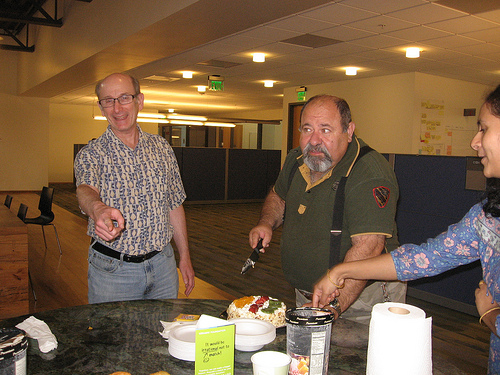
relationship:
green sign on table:
[194, 323, 234, 373] [0, 300, 287, 374]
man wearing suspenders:
[252, 88, 398, 289] [237, 140, 406, 302]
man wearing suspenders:
[75, 73, 195, 303] [282, 143, 374, 269]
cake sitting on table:
[228, 293, 288, 328] [109, 290, 273, 369]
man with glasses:
[84, 60, 199, 283] [99, 91, 139, 108]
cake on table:
[228, 293, 288, 328] [1, 295, 466, 374]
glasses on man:
[98, 88, 142, 108] [71, 71, 195, 303]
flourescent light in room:
[91, 106, 236, 130] [4, 0, 496, 373]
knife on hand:
[240, 245, 265, 272] [248, 217, 273, 245]